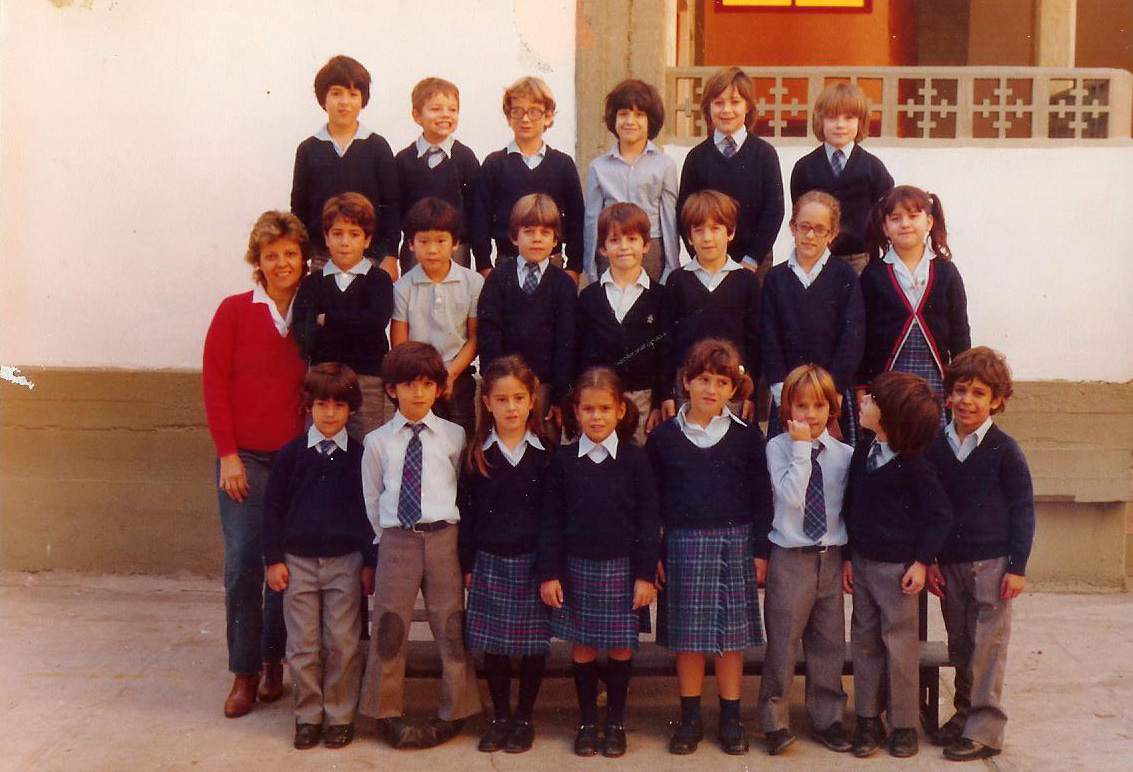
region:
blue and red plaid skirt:
[674, 507, 769, 654]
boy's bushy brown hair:
[933, 325, 1030, 410]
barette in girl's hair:
[711, 341, 764, 378]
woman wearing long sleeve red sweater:
[178, 272, 346, 448]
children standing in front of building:
[191, 39, 1071, 712]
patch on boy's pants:
[358, 589, 432, 669]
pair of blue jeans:
[196, 434, 297, 675]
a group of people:
[305, 83, 1094, 696]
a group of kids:
[154, 37, 913, 731]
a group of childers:
[190, 68, 1072, 653]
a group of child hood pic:
[157, 0, 1055, 527]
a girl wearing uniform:
[607, 400, 807, 689]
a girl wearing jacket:
[86, 202, 378, 706]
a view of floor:
[75, 568, 227, 703]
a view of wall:
[980, 246, 1081, 346]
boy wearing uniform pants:
[938, 339, 1039, 761]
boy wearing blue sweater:
[848, 359, 935, 752]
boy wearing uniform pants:
[848, 356, 949, 750]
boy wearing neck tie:
[755, 352, 847, 737]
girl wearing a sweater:
[538, 365, 654, 746]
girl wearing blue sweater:
[462, 354, 547, 752]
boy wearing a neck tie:
[362, 349, 486, 727]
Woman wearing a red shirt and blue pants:
[202, 206, 326, 715]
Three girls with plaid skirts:
[458, 337, 776, 756]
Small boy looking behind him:
[840, 361, 958, 754]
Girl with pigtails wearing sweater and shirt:
[857, 170, 989, 385]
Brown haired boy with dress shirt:
[574, 76, 680, 266]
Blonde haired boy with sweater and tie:
[780, 76, 919, 271]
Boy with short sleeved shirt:
[380, 206, 493, 393]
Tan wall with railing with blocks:
[666, 58, 1127, 155]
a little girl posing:
[461, 345, 553, 754]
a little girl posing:
[657, 337, 770, 756]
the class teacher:
[204, 213, 309, 721]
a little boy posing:
[363, 344, 463, 748]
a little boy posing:
[936, 345, 1036, 756]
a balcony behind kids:
[672, 51, 1131, 144]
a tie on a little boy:
[803, 436, 824, 542]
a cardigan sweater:
[864, 252, 969, 370]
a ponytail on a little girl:
[925, 192, 946, 250]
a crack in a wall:
[6, 407, 206, 429]